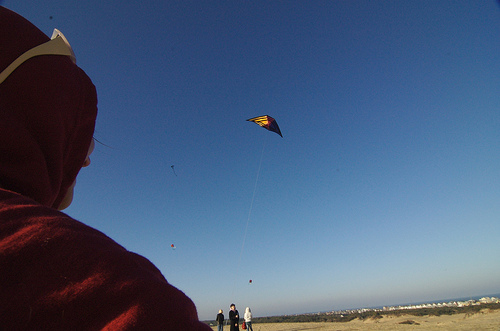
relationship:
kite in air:
[245, 115, 283, 137] [1, 2, 500, 330]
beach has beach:
[199, 309, 500, 329] [199, 309, 500, 330]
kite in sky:
[245, 115, 283, 137] [0, 0, 499, 328]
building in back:
[480, 295, 492, 303] [0, 2, 499, 318]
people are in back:
[216, 304, 255, 331] [0, 2, 499, 318]